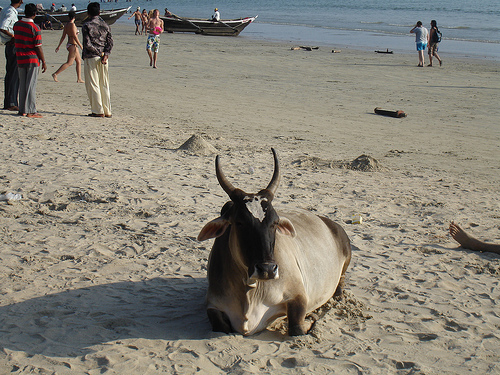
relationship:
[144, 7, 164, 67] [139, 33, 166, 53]
man wearing trunks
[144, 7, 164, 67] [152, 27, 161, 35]
man holding frisbee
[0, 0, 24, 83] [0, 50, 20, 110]
man wearing dark pants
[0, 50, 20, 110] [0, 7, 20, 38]
dark pants wearing white shirt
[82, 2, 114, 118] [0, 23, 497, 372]
man standing beach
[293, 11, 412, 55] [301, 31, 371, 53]
water walking edge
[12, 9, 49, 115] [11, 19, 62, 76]
man wearing shirt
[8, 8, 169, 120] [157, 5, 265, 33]
people in boat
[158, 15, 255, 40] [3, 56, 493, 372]
boat on sand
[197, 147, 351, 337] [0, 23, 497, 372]
bull on beach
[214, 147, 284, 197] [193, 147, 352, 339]
horns on bull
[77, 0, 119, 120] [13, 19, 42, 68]
man wearing shirt